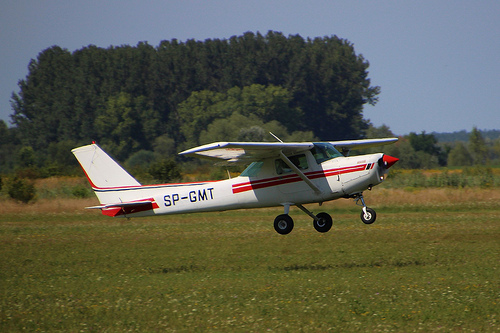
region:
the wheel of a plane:
[360, 206, 375, 221]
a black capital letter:
[160, 190, 174, 208]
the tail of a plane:
[69, 142, 143, 195]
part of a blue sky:
[358, 0, 497, 129]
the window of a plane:
[271, 152, 307, 172]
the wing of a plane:
[171, 136, 311, 161]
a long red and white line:
[221, 160, 364, 195]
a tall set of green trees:
[10, 33, 381, 158]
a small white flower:
[246, 290, 256, 301]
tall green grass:
[407, 167, 498, 187]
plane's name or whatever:
[160, 185, 217, 210]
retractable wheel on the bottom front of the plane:
[347, 184, 379, 227]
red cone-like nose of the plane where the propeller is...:
[380, 150, 400, 171]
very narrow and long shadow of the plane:
[150, 254, 431, 276]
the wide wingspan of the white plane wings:
[175, 135, 403, 165]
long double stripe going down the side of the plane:
[228, 160, 375, 197]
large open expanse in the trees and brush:
[365, 0, 498, 137]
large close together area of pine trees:
[7, 23, 384, 141]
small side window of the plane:
[271, 150, 312, 178]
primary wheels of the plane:
[271, 202, 335, 237]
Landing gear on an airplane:
[347, 190, 379, 222]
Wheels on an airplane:
[265, 205, 330, 231]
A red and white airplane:
[65, 125, 410, 230]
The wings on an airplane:
[170, 125, 397, 157]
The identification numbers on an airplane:
[157, 185, 217, 205]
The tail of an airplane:
[66, 136, 145, 194]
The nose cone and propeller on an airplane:
[376, 147, 401, 171]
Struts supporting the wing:
[266, 141, 329, 199]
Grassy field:
[196, 235, 441, 307]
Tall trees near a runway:
[6, 26, 396, 177]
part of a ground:
[248, 245, 307, 323]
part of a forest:
[272, 21, 324, 82]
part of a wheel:
[363, 215, 388, 243]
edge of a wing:
[223, 115, 266, 156]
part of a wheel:
[321, 210, 335, 233]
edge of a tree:
[369, 79, 379, 98]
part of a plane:
[206, 178, 227, 191]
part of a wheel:
[296, 183, 343, 238]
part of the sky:
[408, 37, 469, 113]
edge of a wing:
[109, 151, 155, 193]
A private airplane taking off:
[36, 112, 426, 249]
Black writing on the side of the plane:
[157, 178, 217, 211]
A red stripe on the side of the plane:
[218, 161, 390, 196]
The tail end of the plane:
[54, 122, 156, 248]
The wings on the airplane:
[173, 125, 417, 163]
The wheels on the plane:
[276, 201, 387, 243]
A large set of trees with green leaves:
[12, 42, 373, 129]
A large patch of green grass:
[11, 235, 485, 323]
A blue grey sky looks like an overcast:
[362, 9, 489, 124]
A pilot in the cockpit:
[283, 152, 309, 174]